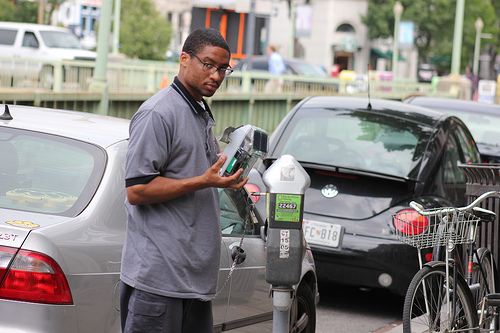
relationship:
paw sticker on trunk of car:
[6, 215, 39, 231] [1, 100, 322, 332]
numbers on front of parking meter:
[278, 201, 297, 211] [261, 154, 309, 285]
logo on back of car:
[321, 180, 337, 200] [243, 89, 483, 301]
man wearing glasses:
[119, 26, 249, 332] [193, 51, 233, 80]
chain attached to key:
[211, 190, 259, 296] [247, 188, 266, 199]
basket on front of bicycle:
[391, 206, 481, 251] [401, 188, 499, 331]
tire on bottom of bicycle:
[400, 259, 478, 332] [401, 188, 499, 331]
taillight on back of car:
[2, 244, 75, 305] [1, 100, 322, 332]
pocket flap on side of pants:
[126, 296, 169, 319] [119, 277, 215, 333]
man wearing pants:
[119, 26, 249, 332] [119, 277, 215, 333]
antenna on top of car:
[1, 76, 14, 121] [1, 100, 322, 332]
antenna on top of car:
[364, 63, 375, 110] [243, 89, 483, 301]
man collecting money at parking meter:
[119, 26, 249, 332] [261, 154, 309, 285]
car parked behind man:
[1, 100, 322, 332] [119, 26, 249, 332]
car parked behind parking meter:
[1, 100, 322, 332] [261, 154, 309, 285]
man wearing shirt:
[263, 41, 286, 90] [267, 50, 285, 73]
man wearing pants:
[263, 41, 286, 90] [261, 73, 286, 94]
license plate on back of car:
[302, 216, 342, 249] [243, 89, 483, 301]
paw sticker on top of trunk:
[6, 215, 39, 231] [0, 209, 70, 287]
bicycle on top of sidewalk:
[401, 188, 499, 331] [383, 300, 461, 332]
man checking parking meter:
[119, 26, 249, 332] [261, 154, 309, 285]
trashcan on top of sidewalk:
[457, 158, 499, 293] [383, 300, 461, 332]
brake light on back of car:
[394, 209, 427, 235] [243, 89, 483, 301]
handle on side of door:
[230, 244, 247, 264] [218, 180, 278, 332]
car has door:
[1, 100, 322, 332] [218, 180, 278, 332]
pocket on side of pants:
[123, 297, 165, 332] [119, 277, 215, 333]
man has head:
[119, 26, 249, 332] [177, 26, 234, 100]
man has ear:
[119, 26, 249, 332] [178, 50, 191, 69]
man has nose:
[119, 26, 249, 332] [210, 69, 221, 83]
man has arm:
[119, 26, 249, 332] [124, 108, 210, 208]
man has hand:
[119, 26, 249, 332] [203, 154, 250, 190]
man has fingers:
[119, 26, 249, 332] [217, 154, 249, 190]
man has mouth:
[119, 26, 249, 332] [203, 80, 219, 91]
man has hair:
[119, 26, 249, 332] [180, 24, 230, 57]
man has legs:
[119, 26, 249, 332] [122, 290, 211, 332]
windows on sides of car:
[273, 108, 478, 183] [243, 89, 483, 301]